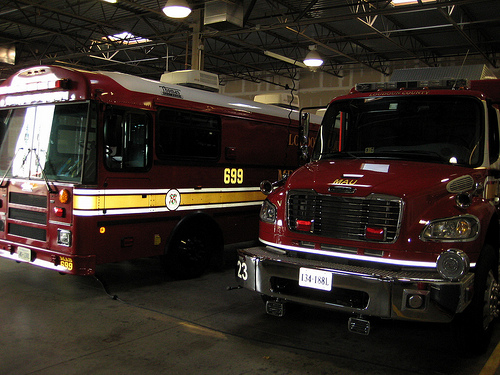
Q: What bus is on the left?
A: The red and gold bus.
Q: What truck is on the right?
A: The red truck.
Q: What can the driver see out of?
A: The windshield.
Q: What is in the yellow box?
A: A bus and a truck.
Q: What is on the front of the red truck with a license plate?
A: The bumper.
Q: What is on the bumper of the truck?
A: A license plate.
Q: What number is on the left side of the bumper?
A: 23.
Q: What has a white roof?
A: The bus.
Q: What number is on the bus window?
A: 699.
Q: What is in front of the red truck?
A: Headlights.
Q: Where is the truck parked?
A: In the garage.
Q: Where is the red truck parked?
A: In a garage with a fire truck.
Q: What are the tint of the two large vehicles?
A: Dark red.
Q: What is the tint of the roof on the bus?
A: White.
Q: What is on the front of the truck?
A: A front window.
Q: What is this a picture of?
A: A fire engine.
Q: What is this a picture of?
A: A fire engine.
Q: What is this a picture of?
A: A fire engine.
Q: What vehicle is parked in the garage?
A: A fire engine.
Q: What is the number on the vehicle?
A: 699.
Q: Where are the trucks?
A: In the garage.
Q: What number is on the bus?
A: 699.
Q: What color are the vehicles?
A: Red.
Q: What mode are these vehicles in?
A: Parked.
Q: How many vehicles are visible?
A: Two.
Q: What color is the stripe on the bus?
A: Yellow.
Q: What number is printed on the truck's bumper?
A: 23.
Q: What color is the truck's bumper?
A: Black.